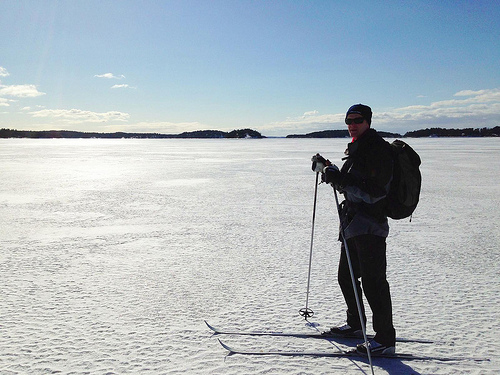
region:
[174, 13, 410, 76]
The open blue sky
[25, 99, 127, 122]
A white cloud in the sky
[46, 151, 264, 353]
Much snow covering the ground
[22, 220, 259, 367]
Tracks are visible throughout the snow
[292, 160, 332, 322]
White skipoles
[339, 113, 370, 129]
Sunglasses on the man's face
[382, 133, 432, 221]
A grey backpack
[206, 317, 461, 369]
Snow covered skis beneath the man's feet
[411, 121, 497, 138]
Trees in the distance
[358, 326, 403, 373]
The man's shadow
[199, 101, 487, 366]
Man skiing on snow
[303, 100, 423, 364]
man wearing a backpack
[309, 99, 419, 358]
man wearing dark pants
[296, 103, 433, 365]
man wearing black and white boots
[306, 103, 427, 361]
man wearing grey jacket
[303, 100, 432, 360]
man wearing wool hat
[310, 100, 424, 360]
man wearing dark sunglasses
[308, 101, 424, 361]
man wearing black gloves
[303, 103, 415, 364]
Man holding ski poles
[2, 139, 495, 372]
snow on level ground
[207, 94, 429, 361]
person posing on skis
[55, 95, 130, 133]
white cloud low in sky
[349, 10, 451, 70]
blue of daytime sky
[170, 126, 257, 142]
trees on distant horizon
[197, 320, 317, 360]
two skis on snow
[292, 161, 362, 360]
hands on two poles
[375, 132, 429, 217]
bag on man's back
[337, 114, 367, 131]
sunglasses on man's face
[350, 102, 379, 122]
hat on man's head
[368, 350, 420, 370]
shadow on top of snow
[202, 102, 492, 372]
A man on snow skis.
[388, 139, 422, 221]
A dark backpack on a man's back.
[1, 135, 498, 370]
White snow on the ground.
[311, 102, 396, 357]
A man in the snow.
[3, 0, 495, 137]
A blue sky with clouds.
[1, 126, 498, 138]
Mountains and trees in the background.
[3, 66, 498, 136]
White clouds in the sky.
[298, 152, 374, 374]
Two poles in a mans hands.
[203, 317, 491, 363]
Two snow skis on the snow.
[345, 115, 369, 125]
A man's black sunglasses.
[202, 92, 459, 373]
The man is on skies.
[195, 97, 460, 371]
The man is cross country skiing.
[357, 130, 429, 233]
The man wears a backpack.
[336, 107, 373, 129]
The man wears sunglasses.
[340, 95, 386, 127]
The man wears a hat.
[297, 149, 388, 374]
The man is holding poles.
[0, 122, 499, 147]
Trees are in the background.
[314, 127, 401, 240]
The man wears a dark jacket.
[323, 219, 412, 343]
The man wears dark pants.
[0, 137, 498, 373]
The ground is covered with snow.